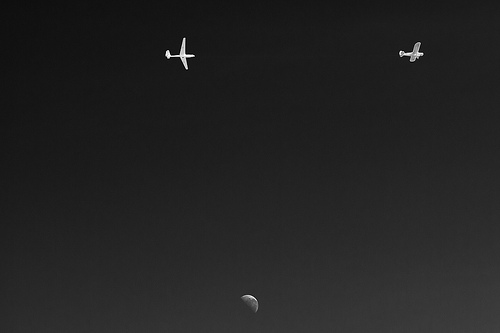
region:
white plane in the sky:
[141, 28, 218, 69]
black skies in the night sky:
[118, 101, 281, 179]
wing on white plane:
[180, 63, 200, 73]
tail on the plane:
[158, 48, 174, 64]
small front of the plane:
[188, 46, 199, 65]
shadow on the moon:
[246, 289, 259, 309]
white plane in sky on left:
[156, 28, 207, 73]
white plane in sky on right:
[378, 33, 429, 70]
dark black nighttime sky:
[128, 80, 270, 197]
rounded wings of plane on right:
[412, 36, 422, 75]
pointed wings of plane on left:
[176, 29, 189, 75]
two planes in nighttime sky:
[146, 24, 438, 106]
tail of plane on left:
[162, 47, 178, 65]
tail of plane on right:
[394, 39, 409, 63]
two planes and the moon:
[159, 18, 426, 320]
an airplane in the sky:
[157, 28, 218, 80]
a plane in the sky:
[393, 38, 433, 69]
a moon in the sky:
[235, 290, 271, 319]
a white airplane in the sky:
[153, 38, 192, 73]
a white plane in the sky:
[159, 38, 206, 77]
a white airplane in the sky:
[379, 36, 431, 61]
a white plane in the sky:
[393, 33, 432, 61]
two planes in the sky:
[150, 23, 440, 87]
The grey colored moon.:
[241, 294, 260, 311]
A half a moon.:
[241, 295, 258, 315]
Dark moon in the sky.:
[239, 295, 259, 314]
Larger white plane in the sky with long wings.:
[162, 37, 195, 71]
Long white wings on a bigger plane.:
[177, 34, 189, 70]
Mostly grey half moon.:
[240, 293, 259, 312]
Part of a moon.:
[239, 294, 259, 312]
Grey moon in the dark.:
[240, 293, 259, 316]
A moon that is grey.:
[239, 294, 260, 316]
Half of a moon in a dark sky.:
[240, 295, 260, 317]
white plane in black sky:
[163, 35, 206, 76]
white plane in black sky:
[394, 41, 430, 60]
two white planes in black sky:
[155, 29, 428, 81]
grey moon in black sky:
[236, 290, 266, 320]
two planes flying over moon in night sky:
[147, 15, 448, 90]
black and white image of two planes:
[13, 10, 495, 317]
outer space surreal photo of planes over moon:
[11, 15, 498, 322]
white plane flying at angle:
[396, 40, 431, 71]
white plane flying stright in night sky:
[161, 35, 199, 76]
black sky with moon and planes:
[7, 19, 497, 324]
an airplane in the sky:
[397, 42, 424, 64]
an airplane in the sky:
[163, 36, 194, 69]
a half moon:
[242, 295, 259, 315]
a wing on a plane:
[180, 36, 188, 55]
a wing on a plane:
[180, 57, 191, 69]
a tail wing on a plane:
[165, 50, 171, 58]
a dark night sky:
[0, 0, 497, 332]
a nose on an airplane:
[185, 52, 193, 59]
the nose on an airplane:
[420, 50, 423, 56]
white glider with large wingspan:
[164, 37, 196, 69]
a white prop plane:
[399, 41, 424, 61]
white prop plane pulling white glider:
[162, 38, 424, 70]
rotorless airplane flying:
[162, 36, 194, 69]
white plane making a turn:
[395, 41, 424, 61]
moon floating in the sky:
[240, 294, 258, 312]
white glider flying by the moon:
[162, 37, 259, 313]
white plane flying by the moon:
[240, 41, 422, 313]